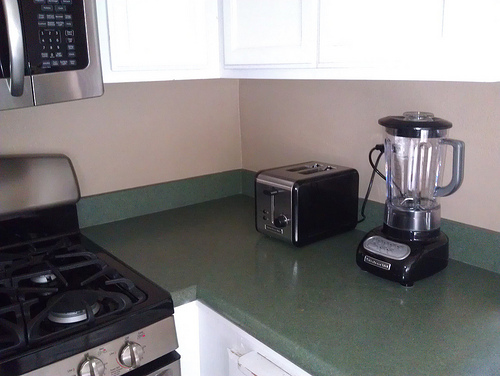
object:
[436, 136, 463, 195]
handle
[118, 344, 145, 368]
dial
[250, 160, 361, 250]
toaster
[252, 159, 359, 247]
appliance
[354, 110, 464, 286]
appliance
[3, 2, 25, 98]
microwave handle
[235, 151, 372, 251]
toaster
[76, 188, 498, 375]
counter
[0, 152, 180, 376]
burner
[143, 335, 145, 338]
light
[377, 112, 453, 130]
cap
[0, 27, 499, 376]
kitchen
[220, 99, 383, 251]
toaster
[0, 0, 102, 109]
microwave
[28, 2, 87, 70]
control pad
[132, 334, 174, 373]
trim